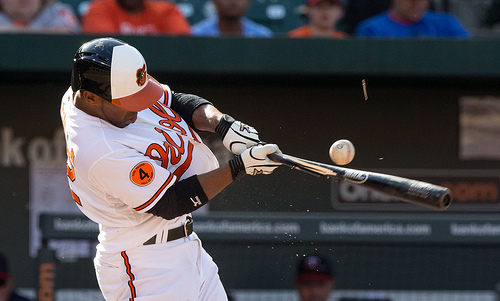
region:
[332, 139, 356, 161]
The baseball being hit by the batter.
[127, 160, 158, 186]
The orange patch on the player's shirt sleeve.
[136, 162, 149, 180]
The number 4 on the orange patch.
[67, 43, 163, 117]
The helmet the batter is wearing.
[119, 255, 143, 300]
The orange stripe on the batter's pants.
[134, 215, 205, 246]
The black belt the batter is wearing.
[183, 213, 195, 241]
The gold buckle of the belt.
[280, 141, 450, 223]
The black bat in the batter's hands.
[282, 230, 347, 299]
The player sitting in the dug out.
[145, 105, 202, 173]
The word on the batter's shirt.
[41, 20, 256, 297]
this is a man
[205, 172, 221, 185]
the man is light skinned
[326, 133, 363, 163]
this is a ball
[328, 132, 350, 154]
the ball is white in color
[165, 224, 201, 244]
this is a belt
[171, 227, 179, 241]
the belt is black in color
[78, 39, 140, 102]
this is the helmet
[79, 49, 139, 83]
the helmet is black and white in color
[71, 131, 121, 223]
this is a t shirt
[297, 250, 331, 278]
this is a cap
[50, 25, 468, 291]
batter swinging at baseball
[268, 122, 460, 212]
black bat hitting baseball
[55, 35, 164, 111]
batting helmet with oriole on it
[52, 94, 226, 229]
white jersey of baseball player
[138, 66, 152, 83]
oriole on front of batting helmet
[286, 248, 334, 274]
hat of man in dugout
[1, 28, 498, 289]
green dugout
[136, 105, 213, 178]
orange text on baseball jersey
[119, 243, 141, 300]
orange stripe on baseball pants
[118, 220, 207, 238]
black belt of baseball player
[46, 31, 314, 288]
This is a person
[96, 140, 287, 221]
Hand of a person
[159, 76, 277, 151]
Hand of a person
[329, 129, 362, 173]
This is a tennis ball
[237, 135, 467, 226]
This is a tennis button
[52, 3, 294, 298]
This is a man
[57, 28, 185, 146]
Head of a man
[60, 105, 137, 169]
Shoulder of a man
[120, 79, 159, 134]
Face of a man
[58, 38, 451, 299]
A baseball player swinging a bat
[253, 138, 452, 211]
A cracking baseball bat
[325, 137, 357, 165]
A baseball in the air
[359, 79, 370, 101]
A splinter from the bat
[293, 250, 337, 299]
A person in a black and red cap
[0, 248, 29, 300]
A person in a black and red cap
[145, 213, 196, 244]
A black cloth belt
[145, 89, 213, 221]
A black undershirt on the player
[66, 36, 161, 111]
A baseball helmet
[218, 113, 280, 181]
a pair of white baseball gloves